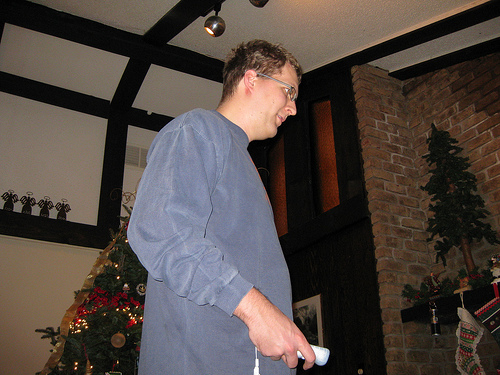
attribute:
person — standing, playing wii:
[124, 38, 332, 374]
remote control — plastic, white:
[285, 340, 332, 367]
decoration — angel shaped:
[54, 195, 72, 222]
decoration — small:
[38, 194, 57, 218]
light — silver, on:
[200, 2, 226, 38]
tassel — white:
[250, 346, 262, 374]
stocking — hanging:
[450, 291, 487, 374]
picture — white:
[290, 290, 325, 348]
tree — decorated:
[36, 203, 148, 374]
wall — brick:
[352, 64, 479, 374]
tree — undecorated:
[420, 120, 498, 280]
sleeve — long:
[124, 107, 256, 317]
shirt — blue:
[125, 107, 299, 374]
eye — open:
[280, 85, 293, 96]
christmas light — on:
[114, 305, 122, 312]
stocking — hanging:
[468, 298, 498, 345]